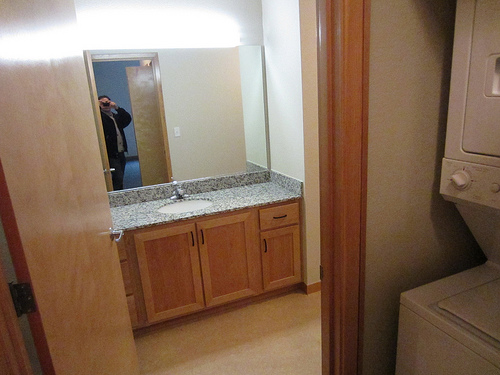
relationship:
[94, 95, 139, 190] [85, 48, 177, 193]
man in front of mirror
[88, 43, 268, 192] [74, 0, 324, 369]
large mirror in bathroom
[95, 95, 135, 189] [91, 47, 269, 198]
photographer seen in mirror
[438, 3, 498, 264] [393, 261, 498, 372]
dryer stacked on washer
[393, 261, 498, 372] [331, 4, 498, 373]
washer in room corner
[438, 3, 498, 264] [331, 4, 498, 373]
dryer in room corner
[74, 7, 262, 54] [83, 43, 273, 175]
bright light on top of large mirror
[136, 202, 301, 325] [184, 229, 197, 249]
cabinet with handle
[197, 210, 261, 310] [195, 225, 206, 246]
cabinet with handle